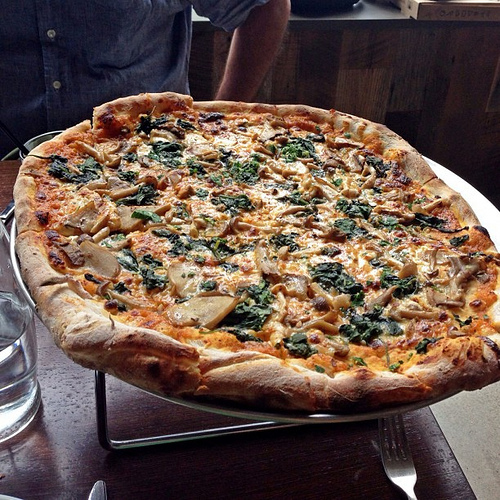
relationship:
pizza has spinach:
[8, 82, 500, 422] [309, 257, 367, 302]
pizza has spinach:
[8, 82, 500, 422] [338, 309, 400, 342]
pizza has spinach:
[8, 82, 500, 422] [236, 279, 275, 331]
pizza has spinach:
[8, 82, 500, 422] [283, 329, 316, 361]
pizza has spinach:
[8, 82, 500, 422] [378, 260, 421, 296]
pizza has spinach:
[8, 82, 500, 422] [335, 216, 374, 239]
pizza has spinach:
[8, 82, 500, 422] [187, 232, 237, 264]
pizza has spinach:
[8, 82, 500, 422] [42, 154, 103, 188]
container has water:
[0, 223, 44, 453] [1, 304, 44, 446]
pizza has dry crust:
[8, 82, 500, 422] [85, 89, 347, 121]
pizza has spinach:
[8, 82, 500, 422] [225, 151, 268, 190]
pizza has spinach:
[8, 82, 500, 422] [211, 187, 251, 217]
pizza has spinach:
[8, 82, 500, 422] [279, 185, 326, 217]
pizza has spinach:
[8, 82, 500, 422] [334, 198, 379, 220]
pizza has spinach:
[8, 82, 500, 422] [133, 251, 169, 292]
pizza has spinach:
[8, 82, 500, 422] [111, 177, 161, 210]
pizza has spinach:
[8, 82, 500, 422] [375, 213, 401, 235]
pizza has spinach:
[8, 82, 500, 422] [45, 151, 77, 183]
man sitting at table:
[5, 1, 257, 91] [6, 414, 467, 495]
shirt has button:
[5, 1, 257, 91] [50, 77, 65, 94]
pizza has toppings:
[8, 82, 500, 422] [67, 121, 455, 350]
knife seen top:
[81, 472, 113, 498] [87, 476, 109, 498]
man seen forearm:
[6, 2, 305, 93] [199, 2, 309, 98]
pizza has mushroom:
[8, 82, 500, 422] [163, 285, 242, 337]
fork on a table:
[373, 410, 424, 500] [6, 414, 467, 495]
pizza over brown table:
[8, 82, 500, 422] [6, 414, 467, 495]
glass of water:
[0, 223, 44, 453] [1, 304, 44, 446]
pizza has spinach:
[8, 82, 500, 422] [200, 279, 221, 291]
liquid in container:
[4, 293, 39, 427] [0, 223, 44, 453]